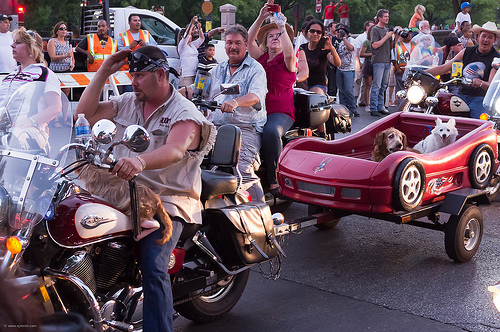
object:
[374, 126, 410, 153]
head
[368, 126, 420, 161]
dog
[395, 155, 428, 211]
wheel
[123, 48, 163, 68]
glasses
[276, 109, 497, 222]
car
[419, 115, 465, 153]
dog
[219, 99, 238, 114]
hand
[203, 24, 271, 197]
man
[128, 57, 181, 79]
bandana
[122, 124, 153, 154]
mirror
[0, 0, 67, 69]
side view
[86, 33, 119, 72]
vest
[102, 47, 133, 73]
hand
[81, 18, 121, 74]
man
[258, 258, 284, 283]
chain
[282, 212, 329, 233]
bar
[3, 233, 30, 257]
headlamp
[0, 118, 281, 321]
motorcycle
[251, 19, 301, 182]
woman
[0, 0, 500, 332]
picture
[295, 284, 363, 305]
cracks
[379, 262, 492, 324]
street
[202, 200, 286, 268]
bag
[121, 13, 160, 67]
men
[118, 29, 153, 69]
vests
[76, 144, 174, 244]
dog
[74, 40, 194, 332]
man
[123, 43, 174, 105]
head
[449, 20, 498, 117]
guy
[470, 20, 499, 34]
cowboy hat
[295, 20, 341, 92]
lady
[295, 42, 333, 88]
t-shirt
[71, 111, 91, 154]
water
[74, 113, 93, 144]
bottle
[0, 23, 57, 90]
female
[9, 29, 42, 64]
head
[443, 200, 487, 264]
wheel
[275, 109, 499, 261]
trailer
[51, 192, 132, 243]
tank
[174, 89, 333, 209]
motorcycle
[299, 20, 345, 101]
people